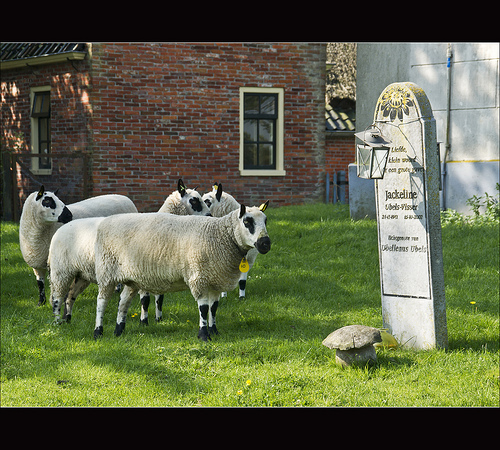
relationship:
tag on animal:
[234, 255, 256, 287] [82, 192, 274, 343]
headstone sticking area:
[348, 79, 452, 349] [0, 203, 500, 409]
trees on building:
[438, 63, 479, 149] [341, 39, 484, 219]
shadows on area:
[66, 334, 268, 389] [14, 327, 297, 394]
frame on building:
[236, 81, 291, 179] [170, 43, 208, 103]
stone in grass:
[353, 83, 453, 355] [9, 331, 302, 397]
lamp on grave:
[354, 122, 391, 179] [284, 303, 428, 373]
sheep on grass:
[9, 170, 272, 342] [3, 321, 318, 404]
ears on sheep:
[230, 193, 248, 223] [82, 191, 269, 345]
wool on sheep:
[125, 224, 174, 246] [18, 179, 278, 337]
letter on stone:
[385, 189, 417, 201] [371, 77, 445, 342]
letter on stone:
[385, 189, 417, 201] [373, 76, 450, 346]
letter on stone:
[385, 189, 417, 201] [381, 183, 415, 203]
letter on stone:
[378, 185, 420, 200] [364, 81, 449, 344]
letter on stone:
[385, 189, 417, 201] [360, 71, 450, 348]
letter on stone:
[385, 189, 417, 201] [364, 81, 449, 344]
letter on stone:
[385, 189, 417, 201] [368, 76, 453, 354]